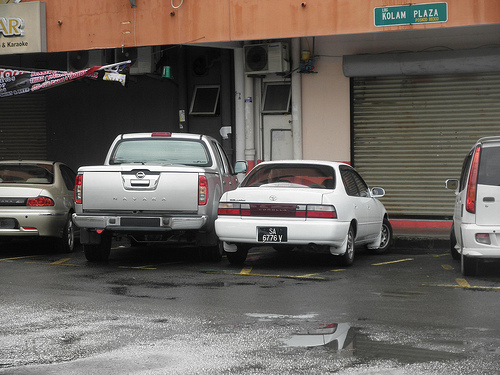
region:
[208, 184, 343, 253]
the tail light on a car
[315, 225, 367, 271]
a back tire on a car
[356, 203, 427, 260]
the front tire on a car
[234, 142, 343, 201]
the back windshield on a car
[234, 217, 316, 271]
a license plate on a car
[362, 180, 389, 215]
a mirror on a car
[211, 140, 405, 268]
a white car in a parking lot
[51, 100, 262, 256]
a truck in a parking lot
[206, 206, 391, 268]
a back bumper on a car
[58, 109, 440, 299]
a car parked next to truck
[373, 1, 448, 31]
Green sign on building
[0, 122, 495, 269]
The vehicles are parked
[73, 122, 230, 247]
The truck is silver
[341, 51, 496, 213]
Grey garage door on side of building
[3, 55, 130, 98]
Black and red twisted banner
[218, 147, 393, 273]
The car is white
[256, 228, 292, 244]
The license plate is black and white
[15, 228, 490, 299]
Yellow lines on the street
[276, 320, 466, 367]
Water puddle in the street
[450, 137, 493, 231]
Long, red light on back of vehicle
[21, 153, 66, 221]
car parked in lot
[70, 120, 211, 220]
truck parked in lot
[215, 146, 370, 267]
car parked in lot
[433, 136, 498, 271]
car parked in lot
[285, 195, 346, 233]
light on a car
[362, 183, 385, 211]
mirror on a car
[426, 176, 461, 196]
mirror on a car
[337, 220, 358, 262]
tire on a car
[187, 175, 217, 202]
light on a truck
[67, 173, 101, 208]
light on a truck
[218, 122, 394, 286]
White car in a parking lot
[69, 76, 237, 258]
Grey pick up truck in a parking lot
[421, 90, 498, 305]
White SUV in a parking lot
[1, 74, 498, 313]
Four cars parked in a parking lot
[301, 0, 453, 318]
Green sign in a parking lot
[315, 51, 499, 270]
Roll up door facing a parking lot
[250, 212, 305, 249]
Dark colored license plates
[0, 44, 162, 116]
Twisted up hanging banner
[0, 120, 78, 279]
Gold colored sedan in a parking lot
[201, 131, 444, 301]
Car parked where there is no parking spot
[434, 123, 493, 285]
Vehicle parked on pavement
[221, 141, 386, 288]
Vehicle parked on pavement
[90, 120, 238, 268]
Vehicle parked on pavement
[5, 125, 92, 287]
Vehicle parked on pavement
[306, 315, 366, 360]
Small water puddle in pavement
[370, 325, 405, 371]
Small water puddle in pavement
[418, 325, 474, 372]
Small water puddle in pavement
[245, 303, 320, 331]
Small water puddle in pavement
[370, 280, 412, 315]
Small water puddle in pavement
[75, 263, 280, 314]
Small water puddle in pavement